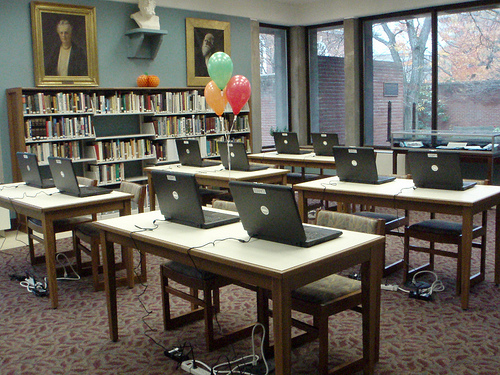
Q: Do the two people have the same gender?
A: No, they are both male and female.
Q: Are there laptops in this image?
A: Yes, there is a laptop.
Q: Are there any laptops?
A: Yes, there is a laptop.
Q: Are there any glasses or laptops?
A: Yes, there is a laptop.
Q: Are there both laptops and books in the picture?
A: Yes, there are both a laptop and a book.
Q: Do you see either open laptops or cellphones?
A: Yes, there is an open laptop.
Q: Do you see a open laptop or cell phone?
A: Yes, there is an open laptop.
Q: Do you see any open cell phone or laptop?
A: Yes, there is an open laptop.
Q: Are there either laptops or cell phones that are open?
A: Yes, the laptop is open.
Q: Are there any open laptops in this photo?
A: Yes, there is an open laptop.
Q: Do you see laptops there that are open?
A: Yes, there is a laptop that is open.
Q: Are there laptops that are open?
A: Yes, there is a laptop that is open.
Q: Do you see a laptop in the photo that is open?
A: Yes, there is a laptop that is open.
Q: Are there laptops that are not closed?
A: Yes, there is a open laptop.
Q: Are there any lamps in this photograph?
A: No, there are no lamps.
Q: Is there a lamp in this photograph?
A: No, there are no lamps.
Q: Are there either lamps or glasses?
A: No, there are no lamps or glasses.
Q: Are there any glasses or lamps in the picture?
A: No, there are no lamps or glasses.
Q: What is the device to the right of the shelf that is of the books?
A: The device is a laptop.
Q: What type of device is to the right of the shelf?
A: The device is a laptop.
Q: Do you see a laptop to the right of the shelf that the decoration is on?
A: Yes, there is a laptop to the right of the shelf.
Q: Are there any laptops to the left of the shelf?
A: No, the laptop is to the right of the shelf.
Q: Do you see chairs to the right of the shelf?
A: No, there is a laptop to the right of the shelf.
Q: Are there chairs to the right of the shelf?
A: No, there is a laptop to the right of the shelf.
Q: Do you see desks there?
A: Yes, there is a desk.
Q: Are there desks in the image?
A: Yes, there is a desk.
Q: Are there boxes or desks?
A: Yes, there is a desk.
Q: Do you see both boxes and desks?
A: No, there is a desk but no boxes.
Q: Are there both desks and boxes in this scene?
A: No, there is a desk but no boxes.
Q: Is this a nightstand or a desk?
A: This is a desk.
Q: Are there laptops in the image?
A: Yes, there is a laptop.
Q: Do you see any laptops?
A: Yes, there is a laptop.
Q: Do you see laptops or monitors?
A: Yes, there is a laptop.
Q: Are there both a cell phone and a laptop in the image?
A: No, there is a laptop but no cell phones.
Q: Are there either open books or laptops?
A: Yes, there is an open laptop.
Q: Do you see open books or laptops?
A: Yes, there is an open laptop.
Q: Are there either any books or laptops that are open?
A: Yes, the laptop is open.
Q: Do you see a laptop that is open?
A: Yes, there is a laptop that is open.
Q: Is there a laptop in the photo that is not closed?
A: Yes, there is a open laptop.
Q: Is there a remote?
A: No, there are no remote controls.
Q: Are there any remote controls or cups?
A: No, there are no remote controls or cups.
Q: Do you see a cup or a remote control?
A: No, there are no remote controls or cups.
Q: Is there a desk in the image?
A: Yes, there is a desk.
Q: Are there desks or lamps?
A: Yes, there is a desk.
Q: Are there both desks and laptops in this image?
A: Yes, there are both a desk and a laptop.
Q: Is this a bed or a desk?
A: This is a desk.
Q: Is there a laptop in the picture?
A: Yes, there is a laptop.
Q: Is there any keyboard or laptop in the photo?
A: Yes, there is a laptop.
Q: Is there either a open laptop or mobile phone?
A: Yes, there is an open laptop.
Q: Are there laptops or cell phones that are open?
A: Yes, the laptop is open.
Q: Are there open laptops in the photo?
A: Yes, there is an open laptop.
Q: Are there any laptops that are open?
A: Yes, there is a laptop that is open.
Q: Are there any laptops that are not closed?
A: Yes, there is a open laptop.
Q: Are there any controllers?
A: No, there are no controllers.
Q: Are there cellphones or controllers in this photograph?
A: No, there are no controllers or cellphones.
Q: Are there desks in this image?
A: Yes, there is a desk.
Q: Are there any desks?
A: Yes, there is a desk.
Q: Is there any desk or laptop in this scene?
A: Yes, there is a desk.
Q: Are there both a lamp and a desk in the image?
A: No, there is a desk but no lamps.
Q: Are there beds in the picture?
A: No, there are no beds.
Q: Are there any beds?
A: No, there are no beds.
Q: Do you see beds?
A: No, there are no beds.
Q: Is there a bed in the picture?
A: No, there are no beds.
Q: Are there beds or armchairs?
A: No, there are no beds or armchairs.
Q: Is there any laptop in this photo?
A: Yes, there is a laptop.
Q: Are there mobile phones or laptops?
A: Yes, there is a laptop.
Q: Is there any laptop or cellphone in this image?
A: Yes, there is a laptop.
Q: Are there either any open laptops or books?
A: Yes, there is an open laptop.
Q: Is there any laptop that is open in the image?
A: Yes, there is an open laptop.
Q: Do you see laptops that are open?
A: Yes, there is a laptop that is open.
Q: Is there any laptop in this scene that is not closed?
A: Yes, there is a open laptop.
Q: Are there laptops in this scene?
A: Yes, there is a laptop.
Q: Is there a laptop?
A: Yes, there is a laptop.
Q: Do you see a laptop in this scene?
A: Yes, there is a laptop.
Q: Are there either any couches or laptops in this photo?
A: Yes, there is a laptop.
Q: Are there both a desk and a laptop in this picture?
A: Yes, there are both a laptop and a desk.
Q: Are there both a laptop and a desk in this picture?
A: Yes, there are both a laptop and a desk.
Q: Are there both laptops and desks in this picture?
A: Yes, there are both a laptop and a desk.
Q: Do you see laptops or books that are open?
A: Yes, the laptop is open.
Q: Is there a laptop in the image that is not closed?
A: Yes, there is a open laptop.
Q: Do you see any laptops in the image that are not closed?
A: Yes, there is a open laptop.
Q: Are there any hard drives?
A: No, there are no hard drives.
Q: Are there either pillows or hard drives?
A: No, there are no hard drives or pillows.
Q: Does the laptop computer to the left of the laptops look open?
A: Yes, the laptop is open.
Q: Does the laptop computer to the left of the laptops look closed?
A: No, the laptop is open.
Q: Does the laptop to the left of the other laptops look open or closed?
A: The laptop is open.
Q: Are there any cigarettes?
A: No, there are no cigarettes.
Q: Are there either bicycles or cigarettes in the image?
A: No, there are no cigarettes or bicycles.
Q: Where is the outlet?
A: The outlet is on the floor.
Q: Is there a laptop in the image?
A: Yes, there is a laptop.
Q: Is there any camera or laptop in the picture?
A: Yes, there is a laptop.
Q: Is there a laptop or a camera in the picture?
A: Yes, there is a laptop.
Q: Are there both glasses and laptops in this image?
A: No, there is a laptop but no glasses.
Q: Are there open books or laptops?
A: Yes, there is an open laptop.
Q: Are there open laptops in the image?
A: Yes, there is an open laptop.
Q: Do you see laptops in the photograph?
A: Yes, there is a laptop.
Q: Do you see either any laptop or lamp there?
A: Yes, there is a laptop.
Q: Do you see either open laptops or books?
A: Yes, there is an open laptop.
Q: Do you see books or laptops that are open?
A: Yes, the laptop is open.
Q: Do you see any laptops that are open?
A: Yes, there is an open laptop.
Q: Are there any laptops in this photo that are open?
A: Yes, there is a laptop that is open.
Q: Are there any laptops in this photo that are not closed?
A: Yes, there is a open laptop.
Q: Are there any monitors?
A: No, there are no monitors.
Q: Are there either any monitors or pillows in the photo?
A: No, there are no monitors or pillows.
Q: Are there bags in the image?
A: No, there are no bags.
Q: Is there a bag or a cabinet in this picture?
A: No, there are no bags or cabinets.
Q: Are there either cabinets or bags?
A: No, there are no bags or cabinets.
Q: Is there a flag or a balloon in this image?
A: Yes, there is a balloon.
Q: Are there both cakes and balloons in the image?
A: No, there is a balloon but no cakes.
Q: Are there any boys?
A: No, there are no boys.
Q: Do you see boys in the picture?
A: No, there are no boys.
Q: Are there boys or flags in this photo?
A: No, there are no boys or flags.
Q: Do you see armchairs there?
A: No, there are no armchairs.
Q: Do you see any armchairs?
A: No, there are no armchairs.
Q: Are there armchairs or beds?
A: No, there are no armchairs or beds.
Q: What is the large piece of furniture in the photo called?
A: The piece of furniture is a shelf.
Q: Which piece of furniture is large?
A: The piece of furniture is a shelf.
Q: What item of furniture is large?
A: The piece of furniture is a shelf.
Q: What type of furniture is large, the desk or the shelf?
A: The shelf is large.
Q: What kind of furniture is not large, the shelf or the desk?
A: The desk is not large.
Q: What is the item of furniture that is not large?
A: The piece of furniture is a desk.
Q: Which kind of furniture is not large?
A: The furniture is a desk.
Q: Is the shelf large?
A: Yes, the shelf is large.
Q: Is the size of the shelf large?
A: Yes, the shelf is large.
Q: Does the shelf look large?
A: Yes, the shelf is large.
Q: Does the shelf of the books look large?
A: Yes, the shelf is large.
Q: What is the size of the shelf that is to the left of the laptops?
A: The shelf is large.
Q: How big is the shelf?
A: The shelf is large.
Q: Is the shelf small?
A: No, the shelf is large.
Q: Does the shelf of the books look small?
A: No, the shelf is large.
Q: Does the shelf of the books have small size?
A: No, the shelf is large.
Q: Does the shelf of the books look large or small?
A: The shelf is large.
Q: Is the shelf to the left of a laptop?
A: Yes, the shelf is to the left of a laptop.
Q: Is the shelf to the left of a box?
A: No, the shelf is to the left of a laptop.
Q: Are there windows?
A: Yes, there is a window.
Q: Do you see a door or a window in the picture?
A: Yes, there is a window.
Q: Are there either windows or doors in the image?
A: Yes, there is a window.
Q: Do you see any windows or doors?
A: Yes, there is a window.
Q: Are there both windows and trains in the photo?
A: No, there is a window but no trains.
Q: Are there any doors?
A: No, there are no doors.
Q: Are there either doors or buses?
A: No, there are no doors or buses.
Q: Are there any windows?
A: Yes, there is a window.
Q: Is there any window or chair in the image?
A: Yes, there is a window.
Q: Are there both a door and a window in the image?
A: No, there is a window but no doors.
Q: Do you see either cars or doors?
A: No, there are no doors or cars.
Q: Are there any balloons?
A: Yes, there is a balloon.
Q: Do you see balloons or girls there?
A: Yes, there is a balloon.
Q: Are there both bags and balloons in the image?
A: No, there is a balloon but no bags.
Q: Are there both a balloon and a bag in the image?
A: No, there is a balloon but no bags.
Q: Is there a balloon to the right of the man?
A: Yes, there is a balloon to the right of the man.